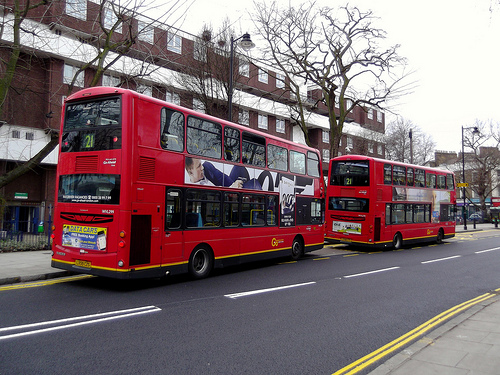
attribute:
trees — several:
[1, 1, 497, 221]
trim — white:
[1, 14, 386, 144]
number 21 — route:
[83, 130, 94, 150]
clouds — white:
[434, 25, 483, 107]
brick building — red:
[8, 2, 398, 150]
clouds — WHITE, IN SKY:
[448, 9, 496, 121]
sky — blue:
[147, 1, 497, 152]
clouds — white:
[106, 0, 499, 162]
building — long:
[0, 0, 389, 237]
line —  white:
[225, 274, 316, 301]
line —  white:
[342, 267, 400, 282]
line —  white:
[421, 253, 462, 270]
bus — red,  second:
[329, 149, 458, 248]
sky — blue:
[378, 21, 470, 102]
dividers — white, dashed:
[223, 282, 323, 304]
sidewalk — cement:
[361, 294, 499, 371]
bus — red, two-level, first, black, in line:
[47, 83, 329, 283]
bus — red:
[339, 150, 479, 263]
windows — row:
[85, 14, 182, 52]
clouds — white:
[350, 9, 488, 111]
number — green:
[78, 125, 95, 150]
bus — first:
[51, 68, 336, 288]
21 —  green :
[344, 176, 353, 186]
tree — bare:
[456, 123, 496, 236]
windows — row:
[161, 105, 321, 172]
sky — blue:
[408, 29, 488, 111]